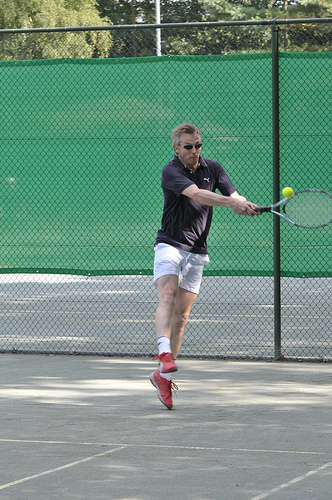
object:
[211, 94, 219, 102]
grey chain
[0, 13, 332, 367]
tall fence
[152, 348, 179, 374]
red shoes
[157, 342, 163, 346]
black socks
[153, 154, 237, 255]
polo shirt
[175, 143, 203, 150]
dark sunglasses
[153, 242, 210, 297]
white shorts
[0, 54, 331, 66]
green barrier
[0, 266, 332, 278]
barrier tied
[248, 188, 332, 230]
tennis racket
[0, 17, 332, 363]
black wire fence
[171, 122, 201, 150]
gray hair on head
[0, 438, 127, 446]
white line on court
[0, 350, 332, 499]
gray asphalt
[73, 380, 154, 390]
light on court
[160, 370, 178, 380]
sole on sneaker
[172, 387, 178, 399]
red sneaker laces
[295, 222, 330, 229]
black trim on racket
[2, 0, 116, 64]
large green tree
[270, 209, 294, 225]
silver tennis rack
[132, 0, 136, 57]
line of trees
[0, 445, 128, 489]
white lines on court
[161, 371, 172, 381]
pair of white socks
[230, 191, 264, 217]
two hand backhand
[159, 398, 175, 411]
touching the ground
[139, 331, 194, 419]
nearly airborn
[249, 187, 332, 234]
racket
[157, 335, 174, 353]
socks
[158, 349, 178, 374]
feet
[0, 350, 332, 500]
court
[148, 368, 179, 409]
sneaker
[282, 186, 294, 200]
ball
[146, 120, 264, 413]
man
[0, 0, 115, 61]
trees